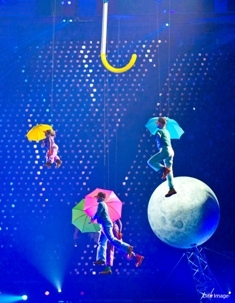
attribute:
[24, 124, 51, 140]
umbrella — yellow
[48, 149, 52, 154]
book — red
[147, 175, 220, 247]
planet — white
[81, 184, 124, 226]
umbrella — pink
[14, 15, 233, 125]
background — blue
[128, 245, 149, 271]
boot — red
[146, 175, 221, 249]
moon — replica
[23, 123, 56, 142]
umbrella — yellow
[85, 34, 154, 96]
handle — white, yellow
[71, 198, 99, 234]
umbrella — green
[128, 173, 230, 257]
planet — light, dark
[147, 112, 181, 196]
people — several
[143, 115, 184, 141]
umbrella — open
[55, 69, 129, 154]
panel — striped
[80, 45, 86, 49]
dots — bright, pale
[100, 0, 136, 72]
handle — silver , yellow 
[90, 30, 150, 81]
object — round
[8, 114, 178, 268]
people — several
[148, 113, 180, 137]
umbrella — blue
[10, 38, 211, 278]
dots — silvery